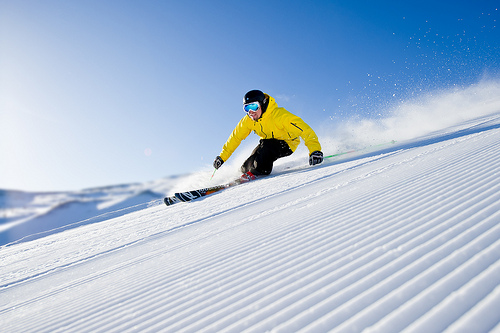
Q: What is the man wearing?
A: Jcaket.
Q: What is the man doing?
A: Skiing.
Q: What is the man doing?
A: Skiing.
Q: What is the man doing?
A: Skiing.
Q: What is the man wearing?
A: Yellow jacket.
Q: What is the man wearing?
A: Yellow jacket.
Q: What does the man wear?
A: Yellow jacket.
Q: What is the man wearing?
A: Yellow jacket.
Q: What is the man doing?
A: Skiing.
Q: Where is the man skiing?
A: On the mountain.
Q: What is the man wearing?
A: Black helmet.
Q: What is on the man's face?
A: Guy wearing a ski mask.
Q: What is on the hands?
A: Guy wearing black gloves.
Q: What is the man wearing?
A: Guy wearing black pants.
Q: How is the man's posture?
A: Guy leaning to the side.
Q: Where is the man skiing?
A: Guy skiing down the hill.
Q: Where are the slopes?
A: In the distance.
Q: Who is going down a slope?
A: The skier.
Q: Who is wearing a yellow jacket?
A: The person.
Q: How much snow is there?
A: Lots of snow.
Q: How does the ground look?
A: Covered in snow.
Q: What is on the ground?
A: Lots of snow.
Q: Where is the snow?
A: On the ground.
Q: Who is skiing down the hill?
A: The man.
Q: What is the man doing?
A: Skiing.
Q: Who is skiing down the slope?
A: The man.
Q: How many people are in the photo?
A: One.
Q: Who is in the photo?
A: A man.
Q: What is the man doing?
A: Skiing.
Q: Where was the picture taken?
A: On a mountain side.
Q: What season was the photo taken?
A: Winter.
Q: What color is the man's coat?
A: Yellow.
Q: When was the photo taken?
A: During the day.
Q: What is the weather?
A: Sunny.